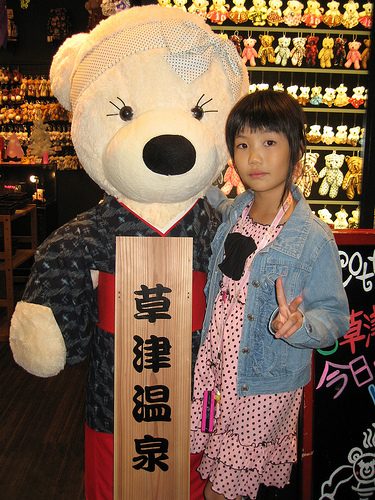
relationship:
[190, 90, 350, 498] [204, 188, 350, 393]
girl has blue jacket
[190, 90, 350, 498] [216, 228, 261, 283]
girl has bow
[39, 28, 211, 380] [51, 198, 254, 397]
bear wear shirt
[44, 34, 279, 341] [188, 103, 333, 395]
bears behind girl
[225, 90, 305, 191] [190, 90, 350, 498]
head on girl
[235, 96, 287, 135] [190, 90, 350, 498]
bangs on girl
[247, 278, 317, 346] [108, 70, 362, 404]
hand on girl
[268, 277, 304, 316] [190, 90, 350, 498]
fingers on girl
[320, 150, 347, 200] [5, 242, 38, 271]
teddy bear on shelf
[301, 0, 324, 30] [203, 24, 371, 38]
teddy bear on shelf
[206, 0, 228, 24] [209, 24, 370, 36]
bear on shelf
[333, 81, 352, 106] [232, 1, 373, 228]
teddy bear on shelf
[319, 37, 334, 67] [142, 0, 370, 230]
teddy bear on shelf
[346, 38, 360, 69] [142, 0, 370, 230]
teddy bear on shelf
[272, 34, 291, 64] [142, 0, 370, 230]
teddy bear on shelf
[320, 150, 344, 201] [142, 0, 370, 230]
teddy bear on shelf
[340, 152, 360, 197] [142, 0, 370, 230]
teddy bear on shelf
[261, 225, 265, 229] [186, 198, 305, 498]
dots on pink dress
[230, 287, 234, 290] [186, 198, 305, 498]
dots on pink dress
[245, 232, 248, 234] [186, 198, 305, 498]
dots on pink dress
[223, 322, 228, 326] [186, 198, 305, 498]
dots on pink dress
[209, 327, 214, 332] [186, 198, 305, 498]
dots on pink dress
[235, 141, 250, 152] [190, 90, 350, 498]
eye of a girl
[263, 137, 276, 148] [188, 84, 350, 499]
eye of a woman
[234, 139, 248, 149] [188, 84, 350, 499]
eye of a woman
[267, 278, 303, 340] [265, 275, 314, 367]
hand making a sign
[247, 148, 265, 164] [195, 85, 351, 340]
nose of a woman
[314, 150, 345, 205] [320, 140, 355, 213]
teddy bear hanging in a shelf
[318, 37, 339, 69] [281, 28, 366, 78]
bear hanging in a shelf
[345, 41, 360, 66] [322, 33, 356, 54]
teddy bear hanging in a shelf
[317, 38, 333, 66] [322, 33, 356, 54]
teddy bear hanging in a shelf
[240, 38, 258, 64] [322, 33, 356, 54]
teddy bear hanging in a shelf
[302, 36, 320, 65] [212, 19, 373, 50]
teddy bear hanging in a shelf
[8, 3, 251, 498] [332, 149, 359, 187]
bear hanging in a shelf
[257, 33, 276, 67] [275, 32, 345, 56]
bear hanging in a shelf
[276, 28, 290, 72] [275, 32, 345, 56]
bear hanging in a shelf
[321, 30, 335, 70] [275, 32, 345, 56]
bear hanging in a shelf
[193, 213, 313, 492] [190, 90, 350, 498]
pink dress on girl